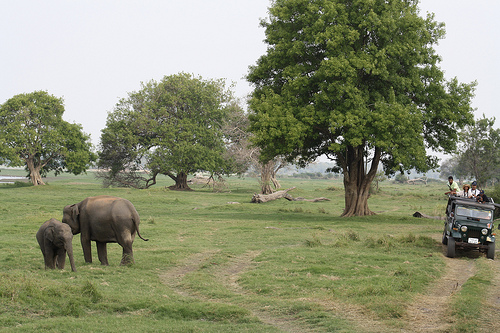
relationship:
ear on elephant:
[65, 200, 78, 218] [32, 216, 83, 277]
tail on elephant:
[130, 207, 144, 243] [63, 185, 161, 247]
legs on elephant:
[76, 249, 109, 270] [39, 197, 151, 267]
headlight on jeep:
[479, 226, 491, 237] [440, 186, 495, 259]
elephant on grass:
[62, 194, 149, 267] [220, 196, 379, 331]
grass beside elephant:
[21, 262, 228, 326] [62, 197, 152, 261]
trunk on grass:
[249, 175, 299, 212] [196, 192, 351, 250]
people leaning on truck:
[443, 176, 489, 202] [443, 197, 493, 259]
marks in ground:
[185, 239, 261, 322] [143, 237, 293, 327]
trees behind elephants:
[235, 0, 470, 237] [43, 198, 144, 277]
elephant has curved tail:
[62, 194, 149, 267] [129, 217, 150, 243]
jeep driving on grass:
[440, 196, 500, 259] [0, 169, 499, 331]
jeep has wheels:
[440, 196, 500, 259] [435, 228, 497, 263]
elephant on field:
[55, 199, 175, 270] [212, 196, 413, 323]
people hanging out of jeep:
[443, 174, 490, 207] [427, 191, 496, 261]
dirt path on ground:
[179, 250, 495, 332] [15, 175, 480, 330]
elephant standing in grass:
[34, 217, 81, 272] [0, 169, 499, 331]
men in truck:
[442, 176, 482, 197] [435, 194, 499, 256]